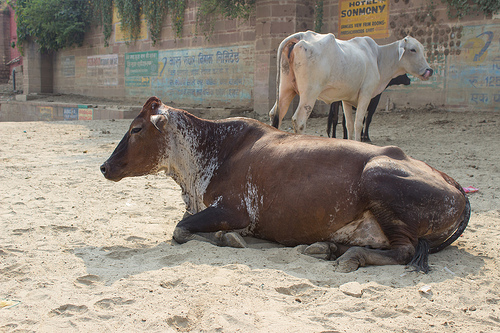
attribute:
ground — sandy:
[2, 119, 499, 327]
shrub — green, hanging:
[5, 1, 90, 48]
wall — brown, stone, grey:
[54, 1, 498, 112]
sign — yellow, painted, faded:
[337, 0, 390, 40]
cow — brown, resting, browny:
[101, 95, 472, 274]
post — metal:
[12, 69, 17, 94]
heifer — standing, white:
[266, 27, 435, 139]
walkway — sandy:
[5, 83, 249, 114]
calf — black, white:
[326, 75, 412, 143]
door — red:
[9, 9, 24, 76]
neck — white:
[164, 106, 215, 198]